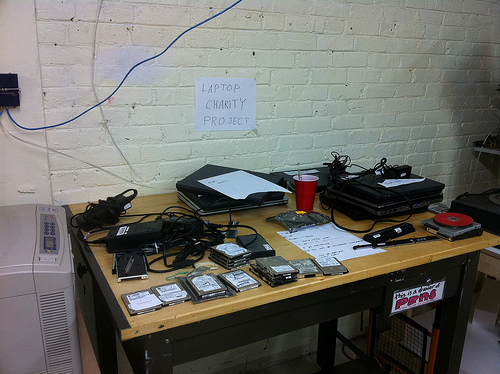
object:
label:
[386, 278, 447, 318]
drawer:
[380, 262, 466, 321]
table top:
[59, 192, 499, 344]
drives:
[80, 197, 258, 282]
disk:
[216, 268, 257, 294]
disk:
[431, 211, 474, 229]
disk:
[118, 288, 166, 317]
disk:
[309, 252, 348, 277]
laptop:
[173, 160, 286, 208]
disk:
[246, 254, 300, 290]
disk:
[205, 241, 253, 272]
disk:
[285, 256, 320, 276]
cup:
[289, 173, 321, 212]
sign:
[193, 77, 258, 133]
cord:
[0, 0, 244, 131]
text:
[199, 83, 248, 129]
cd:
[196, 168, 295, 201]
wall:
[0, 0, 498, 373]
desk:
[57, 191, 498, 374]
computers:
[316, 162, 446, 222]